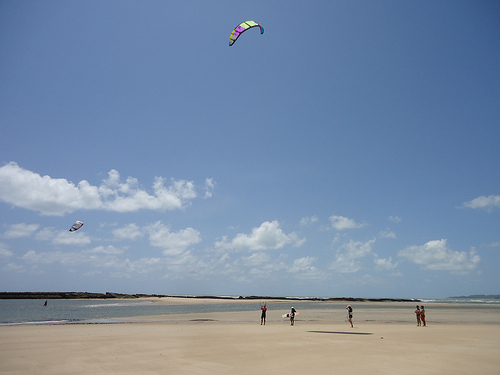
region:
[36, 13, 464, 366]
people flying kites at the beach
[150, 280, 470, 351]
people standing on sand near water's edge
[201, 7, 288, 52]
curved kite with purple and green panels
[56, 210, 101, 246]
white kite bordered with color at curved edge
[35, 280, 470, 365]
wide expanse of sand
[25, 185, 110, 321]
person in water underneath kite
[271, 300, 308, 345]
person holding surfboard at beach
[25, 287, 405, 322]
shallow water along beach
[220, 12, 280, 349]
person controlling strings under kite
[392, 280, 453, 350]
two people standing together at the beach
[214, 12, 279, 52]
A kite fyling high in the air.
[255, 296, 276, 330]
Man holding string to a kite.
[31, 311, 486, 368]
A sandy beach.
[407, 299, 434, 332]
Two women are standing together.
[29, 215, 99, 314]
A man in the water flying a kite.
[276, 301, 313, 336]
Person holding a surf board.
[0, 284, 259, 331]
Ocean water.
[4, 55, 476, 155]
Blue sky.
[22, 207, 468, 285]
Kite is flying amid several white clouds.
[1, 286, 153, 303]
A small section of rocks in background.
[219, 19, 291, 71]
a kite in the sky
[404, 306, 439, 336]
a couple watching the kite fly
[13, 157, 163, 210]
thick white clouds in the sky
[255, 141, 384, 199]
cleat blue color of the sky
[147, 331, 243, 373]
smooth white sand on the beach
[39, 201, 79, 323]
a person parasailing over the ocean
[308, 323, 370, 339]
a shadow on the sand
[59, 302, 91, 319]
peaceful blue water of the ocean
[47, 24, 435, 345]
people enjoying a day at the beach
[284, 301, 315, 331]
a person holding a surfboard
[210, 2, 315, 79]
Kite in the sky.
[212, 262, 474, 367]
People on the beach.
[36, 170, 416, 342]
Clouds in the sky.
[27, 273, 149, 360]
Water on the beach.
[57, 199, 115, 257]
Kite under the clouds.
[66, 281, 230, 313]
Trees in the background.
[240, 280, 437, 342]
Five people on the beach.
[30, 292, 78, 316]
Person in the water.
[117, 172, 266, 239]
White fluffy clouds in the sky.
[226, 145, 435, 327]
Blue sky with clouds.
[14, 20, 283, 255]
two kites in the sky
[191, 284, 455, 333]
five people on the beach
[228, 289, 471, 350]
two people flying kites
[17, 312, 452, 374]
sand on the beach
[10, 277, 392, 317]
water at the beach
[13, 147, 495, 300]
clouds in the sky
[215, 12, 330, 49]
a multi-colored kite in the sky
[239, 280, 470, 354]
five people at the beach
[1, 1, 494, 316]
blue skies with a few clouds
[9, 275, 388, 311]
rocks near the ocean